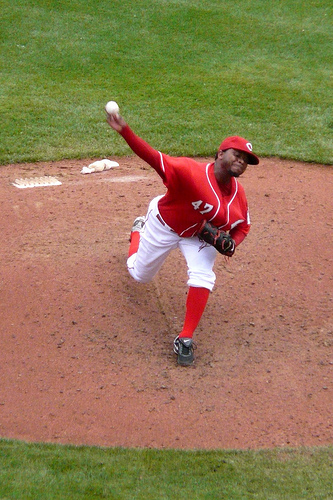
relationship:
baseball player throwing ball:
[97, 114, 260, 367] [105, 99, 119, 117]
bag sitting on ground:
[81, 160, 106, 174] [1, 0, 333, 500]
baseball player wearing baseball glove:
[97, 114, 260, 367] [195, 219, 235, 257]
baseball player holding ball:
[97, 114, 260, 367] [105, 99, 119, 117]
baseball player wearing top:
[97, 114, 260, 367] [156, 150, 251, 247]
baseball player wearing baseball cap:
[97, 114, 260, 367] [217, 134, 259, 165]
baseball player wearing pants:
[97, 114, 260, 367] [125, 193, 220, 292]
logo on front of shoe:
[182, 338, 191, 344] [171, 334, 197, 367]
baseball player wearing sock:
[97, 114, 260, 367] [177, 286, 211, 341]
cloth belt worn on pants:
[156, 213, 177, 234] [125, 193, 220, 292]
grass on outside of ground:
[1, 0, 332, 166] [1, 0, 333, 500]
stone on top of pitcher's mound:
[159, 383, 168, 390] [1, 155, 333, 449]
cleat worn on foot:
[142, 215, 147, 220] [128, 217, 146, 244]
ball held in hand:
[105, 99, 119, 117] [104, 104, 128, 132]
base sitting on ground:
[11, 174, 63, 191] [1, 0, 333, 500]